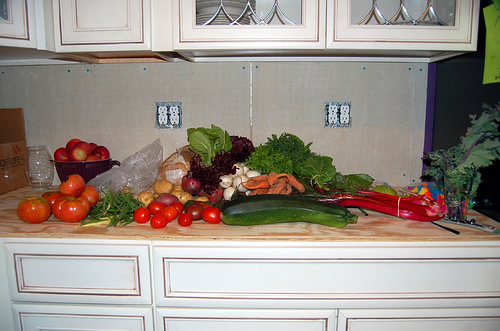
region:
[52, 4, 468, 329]
the scene is in a kitchen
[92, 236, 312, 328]
the drawers are white in colour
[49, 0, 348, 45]
the cupboard is white in colour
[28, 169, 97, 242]
the tomatoes are red in colour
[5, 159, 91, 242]
the tomatoes are ripe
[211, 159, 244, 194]
the garlic is white in coloue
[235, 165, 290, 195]
the carrots are orange in colour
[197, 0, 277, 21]
plates are inside the cupboard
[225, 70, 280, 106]
the wall is brown in colour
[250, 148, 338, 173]
veggetables are green in colour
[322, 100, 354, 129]
an uncovered electrical outlet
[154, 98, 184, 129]
an uncovered electrical outlet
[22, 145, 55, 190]
a glass jar on a counter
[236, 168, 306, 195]
a pile of carrots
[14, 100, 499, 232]
some vegetables on a counter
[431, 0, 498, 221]
a black refrigerator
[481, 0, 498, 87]
a piece of green paper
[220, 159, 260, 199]
a pile of onions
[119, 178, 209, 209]
a pile of potatoes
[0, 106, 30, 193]
a cardboard box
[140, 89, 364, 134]
several power outlets without covers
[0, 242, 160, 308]
kitchen cabinet drawer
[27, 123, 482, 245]
several vegetables in pile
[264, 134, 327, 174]
bunches of green parsley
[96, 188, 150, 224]
pile of green beans on table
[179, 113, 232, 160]
fresh spinag in bunches on table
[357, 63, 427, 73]
three nail holes on wall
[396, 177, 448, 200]
bag of balloons on table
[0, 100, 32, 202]
paper box on kitchen table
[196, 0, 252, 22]
large stack of plates in cabinet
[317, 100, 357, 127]
dual electric outlet on wall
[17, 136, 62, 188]
glass empty jar on table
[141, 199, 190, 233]
several tomato's on table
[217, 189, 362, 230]
green cucumber on counter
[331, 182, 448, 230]
bunch of radishes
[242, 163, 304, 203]
bunch of carets stacked on counter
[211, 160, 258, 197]
several white onions mounded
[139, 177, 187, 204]
several potatoes on counter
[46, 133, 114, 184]
several apples in purple jar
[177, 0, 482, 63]
two white cabinet doors with glass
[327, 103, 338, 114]
the outlet in the wall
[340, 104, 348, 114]
the outlet in the wall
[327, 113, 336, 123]
the outlet in the wall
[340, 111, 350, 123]
the outlet in the wall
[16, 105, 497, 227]
the food on the counter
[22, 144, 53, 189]
the clear jar on the counter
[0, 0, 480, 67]
the cabinets above the food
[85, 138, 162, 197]
the clear plastic bag on the counter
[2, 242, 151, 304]
the drawer under the counter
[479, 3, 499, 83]
the green paper hanging